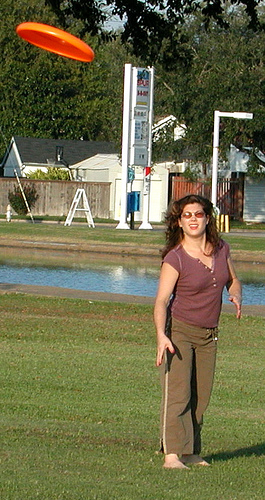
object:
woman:
[151, 196, 240, 469]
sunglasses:
[176, 210, 205, 220]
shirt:
[159, 238, 230, 334]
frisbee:
[15, 17, 94, 66]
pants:
[158, 321, 218, 453]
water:
[0, 251, 265, 308]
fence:
[0, 176, 242, 218]